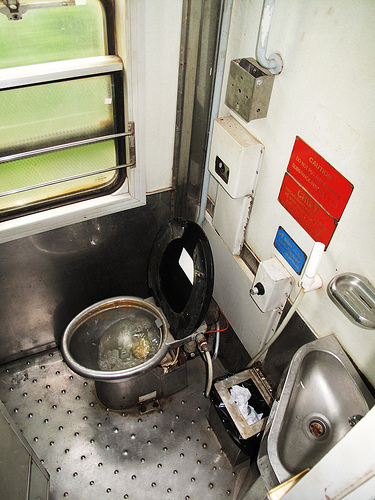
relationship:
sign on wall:
[271, 226, 307, 276] [193, 33, 373, 367]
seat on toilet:
[144, 215, 212, 339] [57, 215, 211, 410]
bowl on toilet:
[59, 293, 169, 379] [57, 215, 211, 410]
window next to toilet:
[0, 0, 134, 217] [68, 280, 184, 382]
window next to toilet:
[32, 38, 135, 157] [56, 260, 207, 370]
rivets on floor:
[33, 398, 184, 473] [102, 428, 155, 466]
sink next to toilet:
[273, 341, 348, 466] [35, 31, 366, 460]